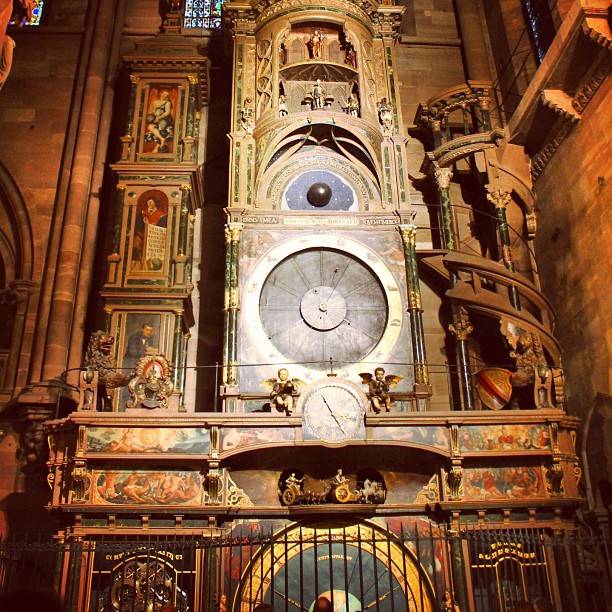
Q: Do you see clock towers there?
A: Yes, there is a clock tower.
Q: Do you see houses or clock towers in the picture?
A: Yes, there is a clock tower.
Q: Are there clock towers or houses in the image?
A: Yes, there is a clock tower.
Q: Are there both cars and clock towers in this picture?
A: No, there is a clock tower but no cars.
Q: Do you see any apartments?
A: No, there are no apartments.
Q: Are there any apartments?
A: No, there are no apartments.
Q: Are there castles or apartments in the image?
A: No, there are no apartments or castles.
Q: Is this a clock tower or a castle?
A: This is a clock tower.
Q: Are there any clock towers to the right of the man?
A: Yes, there is a clock tower to the right of the man.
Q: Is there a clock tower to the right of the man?
A: Yes, there is a clock tower to the right of the man.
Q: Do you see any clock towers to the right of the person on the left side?
A: Yes, there is a clock tower to the right of the man.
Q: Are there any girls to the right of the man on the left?
A: No, there is a clock tower to the right of the man.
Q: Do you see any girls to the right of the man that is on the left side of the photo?
A: No, there is a clock tower to the right of the man.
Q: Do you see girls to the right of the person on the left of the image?
A: No, there is a clock tower to the right of the man.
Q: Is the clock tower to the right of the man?
A: Yes, the clock tower is to the right of the man.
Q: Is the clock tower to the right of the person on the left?
A: Yes, the clock tower is to the right of the man.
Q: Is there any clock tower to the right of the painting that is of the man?
A: Yes, there is a clock tower to the right of the painting.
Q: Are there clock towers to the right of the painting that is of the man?
A: Yes, there is a clock tower to the right of the painting.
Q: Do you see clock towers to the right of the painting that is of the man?
A: Yes, there is a clock tower to the right of the painting.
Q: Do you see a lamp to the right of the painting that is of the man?
A: No, there is a clock tower to the right of the painting.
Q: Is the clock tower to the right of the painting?
A: Yes, the clock tower is to the right of the painting.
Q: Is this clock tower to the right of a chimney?
A: No, the clock tower is to the right of the painting.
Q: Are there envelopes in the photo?
A: No, there are no envelopes.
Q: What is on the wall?
A: The decoration is on the wall.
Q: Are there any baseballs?
A: No, there are no baseballs.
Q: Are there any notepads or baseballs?
A: No, there are no baseballs or notepads.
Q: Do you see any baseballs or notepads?
A: No, there are no baseballs or notepads.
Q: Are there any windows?
A: Yes, there is a window.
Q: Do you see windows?
A: Yes, there is a window.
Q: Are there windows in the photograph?
A: Yes, there is a window.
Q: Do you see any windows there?
A: Yes, there is a window.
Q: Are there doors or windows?
A: Yes, there is a window.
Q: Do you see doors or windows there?
A: Yes, there is a window.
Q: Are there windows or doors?
A: Yes, there is a window.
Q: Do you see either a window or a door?
A: Yes, there is a window.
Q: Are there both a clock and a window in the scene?
A: Yes, there are both a window and a clock.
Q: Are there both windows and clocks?
A: Yes, there are both a window and a clock.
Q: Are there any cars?
A: No, there are no cars.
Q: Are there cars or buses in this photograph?
A: No, there are no cars or buses.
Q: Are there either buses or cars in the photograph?
A: No, there are no cars or buses.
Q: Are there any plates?
A: No, there are no plates.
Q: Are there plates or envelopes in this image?
A: No, there are no plates or envelopes.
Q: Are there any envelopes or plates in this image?
A: No, there are no plates or envelopes.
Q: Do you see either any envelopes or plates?
A: No, there are no plates or envelopes.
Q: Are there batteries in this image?
A: No, there are no batteries.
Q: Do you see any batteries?
A: No, there are no batteries.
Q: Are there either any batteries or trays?
A: No, there are no batteries or trays.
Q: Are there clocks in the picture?
A: Yes, there is a clock.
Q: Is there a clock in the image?
A: Yes, there is a clock.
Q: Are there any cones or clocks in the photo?
A: Yes, there is a clock.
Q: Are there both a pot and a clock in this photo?
A: No, there is a clock but no pots.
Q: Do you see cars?
A: No, there are no cars.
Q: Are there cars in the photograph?
A: No, there are no cars.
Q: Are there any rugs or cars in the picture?
A: No, there are no cars or rugs.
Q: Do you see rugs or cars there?
A: No, there are no cars or rugs.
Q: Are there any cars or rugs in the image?
A: No, there are no cars or rugs.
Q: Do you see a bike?
A: No, there are no bikes.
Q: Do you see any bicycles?
A: No, there are no bicycles.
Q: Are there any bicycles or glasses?
A: No, there are no bicycles or glasses.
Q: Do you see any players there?
A: No, there are no players.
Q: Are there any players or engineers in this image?
A: No, there are no players or engineers.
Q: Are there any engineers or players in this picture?
A: No, there are no players or engineers.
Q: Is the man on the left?
A: Yes, the man is on the left of the image.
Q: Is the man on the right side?
A: No, the man is on the left of the image.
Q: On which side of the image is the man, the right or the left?
A: The man is on the left of the image.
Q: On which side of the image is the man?
A: The man is on the left of the image.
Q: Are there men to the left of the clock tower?
A: Yes, there is a man to the left of the clock tower.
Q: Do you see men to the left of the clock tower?
A: Yes, there is a man to the left of the clock tower.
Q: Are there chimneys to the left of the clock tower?
A: No, there is a man to the left of the clock tower.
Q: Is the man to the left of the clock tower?
A: Yes, the man is to the left of the clock tower.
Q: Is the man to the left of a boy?
A: No, the man is to the left of the clock tower.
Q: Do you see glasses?
A: No, there are no glasses.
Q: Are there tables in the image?
A: No, there are no tables.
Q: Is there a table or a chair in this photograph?
A: No, there are no tables or chairs.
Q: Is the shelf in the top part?
A: Yes, the shelf is in the top of the image.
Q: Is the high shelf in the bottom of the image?
A: No, the shelf is in the top of the image.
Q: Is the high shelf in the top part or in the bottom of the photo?
A: The shelf is in the top of the image.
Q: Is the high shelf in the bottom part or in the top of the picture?
A: The shelf is in the top of the image.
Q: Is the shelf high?
A: Yes, the shelf is high.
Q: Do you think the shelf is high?
A: Yes, the shelf is high.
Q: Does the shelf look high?
A: Yes, the shelf is high.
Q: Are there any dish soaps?
A: No, there are no dish soaps.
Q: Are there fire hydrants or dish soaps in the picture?
A: No, there are no dish soaps or fire hydrants.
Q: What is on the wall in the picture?
A: The decoration is on the wall.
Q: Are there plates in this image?
A: No, there are no plates.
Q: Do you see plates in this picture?
A: No, there are no plates.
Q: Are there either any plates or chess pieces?
A: No, there are no plates or chess pieces.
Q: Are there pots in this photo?
A: No, there are no pots.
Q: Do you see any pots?
A: No, there are no pots.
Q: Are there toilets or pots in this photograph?
A: No, there are no pots or toilets.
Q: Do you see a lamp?
A: No, there are no lamps.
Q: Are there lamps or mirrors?
A: No, there are no lamps or mirrors.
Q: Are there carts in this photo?
A: No, there are no carts.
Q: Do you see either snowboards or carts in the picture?
A: No, there are no carts or snowboards.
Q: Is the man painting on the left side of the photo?
A: Yes, the painting is on the left of the image.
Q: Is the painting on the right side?
A: No, the painting is on the left of the image.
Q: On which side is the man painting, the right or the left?
A: The painting is on the left of the image.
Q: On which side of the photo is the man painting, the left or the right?
A: The painting is on the left of the image.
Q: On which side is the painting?
A: The painting is on the left of the image.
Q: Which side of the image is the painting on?
A: The painting is on the left of the image.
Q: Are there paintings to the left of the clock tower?
A: Yes, there is a painting to the left of the clock tower.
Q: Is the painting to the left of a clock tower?
A: Yes, the painting is to the left of a clock tower.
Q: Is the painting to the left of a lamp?
A: No, the painting is to the left of a clock tower.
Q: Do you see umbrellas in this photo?
A: No, there are no umbrellas.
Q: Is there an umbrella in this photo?
A: No, there are no umbrellas.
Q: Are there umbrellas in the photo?
A: No, there are no umbrellas.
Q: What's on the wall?
A: The decoration is on the wall.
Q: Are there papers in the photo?
A: No, there are no papers.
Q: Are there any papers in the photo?
A: No, there are no papers.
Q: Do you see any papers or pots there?
A: No, there are no papers or pots.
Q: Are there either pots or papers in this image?
A: No, there are no papers or pots.